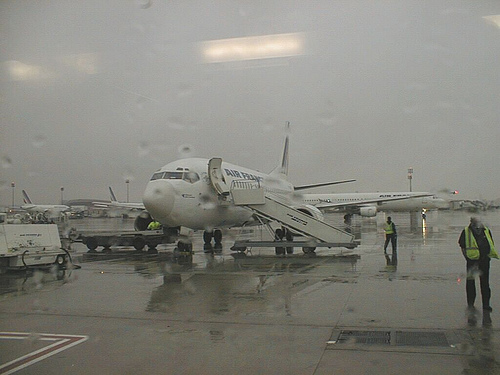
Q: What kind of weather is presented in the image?
A: Rain.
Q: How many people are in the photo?
A: 3.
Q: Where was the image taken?
A: A airport.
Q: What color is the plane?
A: White.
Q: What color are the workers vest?
A: Yellow.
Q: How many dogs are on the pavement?
A: 0.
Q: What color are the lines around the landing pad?
A: Red and white.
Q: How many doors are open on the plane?
A: 1.